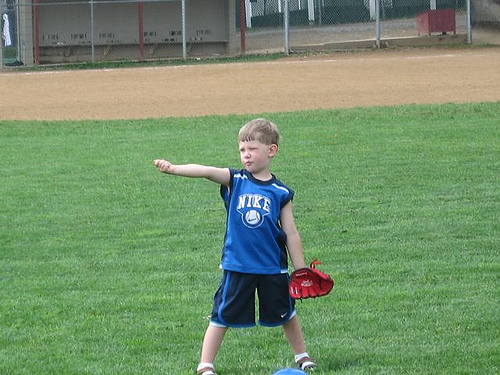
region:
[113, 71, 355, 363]
boy in the grass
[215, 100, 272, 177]
head of the boy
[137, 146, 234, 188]
arm of the boy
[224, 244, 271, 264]
the shirt is blue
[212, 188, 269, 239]
logo on the shirt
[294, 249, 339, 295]
mitt on the hand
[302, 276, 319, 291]
the mitt is red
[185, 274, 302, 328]
shorts on the boy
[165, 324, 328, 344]
legs of the boy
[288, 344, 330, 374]
sandal on the boy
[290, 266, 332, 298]
The boy is wearing a red glove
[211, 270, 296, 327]
The boy is wearing shorts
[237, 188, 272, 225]
A Nike logo on the shirt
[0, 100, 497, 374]
Grass on the baseball field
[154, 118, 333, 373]
A boy standing in a baseball field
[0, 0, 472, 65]
A fence near the dugout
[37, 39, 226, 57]
A bench in the dugout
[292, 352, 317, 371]
The boy is wearing sandals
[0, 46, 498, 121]
Dirt near the infield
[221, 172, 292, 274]
The boy is wearing a blue shirt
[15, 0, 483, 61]
a metal chain link fence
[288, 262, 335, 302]
a red baseball mit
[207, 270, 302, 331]
a pair of nike shorts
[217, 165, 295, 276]
a blue athletic jersey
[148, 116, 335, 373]
a small boy standing on the grass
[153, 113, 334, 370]
a boy playing baseball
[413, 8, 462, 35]
a large red bin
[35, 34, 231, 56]
a bench in the dugout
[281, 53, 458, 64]
a white line in the dirt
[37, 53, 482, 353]
a well groomed baseball field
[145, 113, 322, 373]
boy playing baseball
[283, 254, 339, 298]
catcher's mit on the boy's hand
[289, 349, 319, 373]
left leg on the boy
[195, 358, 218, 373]
right foot on the boy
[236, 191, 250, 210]
the letter N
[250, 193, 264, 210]
the letter K on the shirt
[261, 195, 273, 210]
the letter E on the shirt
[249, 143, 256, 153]
a boy's eye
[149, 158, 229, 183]
the boy's arm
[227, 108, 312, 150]
The little boy has light hair.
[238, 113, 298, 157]
The boys hair is blonde.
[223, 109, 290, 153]
The boys hair is short.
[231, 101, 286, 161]
The boys hair is straight.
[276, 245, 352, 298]
The boy is wearing a baseball glove.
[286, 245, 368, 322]
The baseball glove is small.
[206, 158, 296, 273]
The boy is wearing a blue shirt.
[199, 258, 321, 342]
The boy is wearing blue shorts.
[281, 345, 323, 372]
The boys sandal is brown.